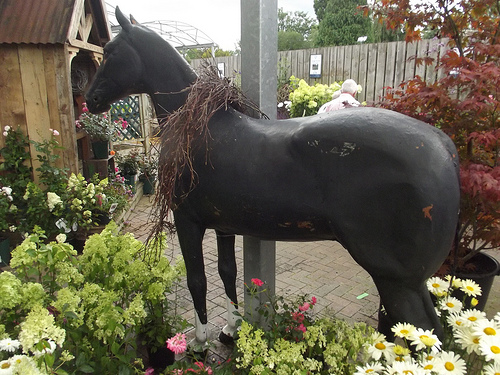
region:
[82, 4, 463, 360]
black statue of a horse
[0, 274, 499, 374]
white daisies around statue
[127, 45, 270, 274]
brown branches on statue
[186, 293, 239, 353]
statue has two white spots on legs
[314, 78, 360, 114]
older man behind statue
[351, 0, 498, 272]
red tree behind statue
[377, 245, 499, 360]
red tree in black pot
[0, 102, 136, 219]
roses behind statue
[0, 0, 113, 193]
wooden shed behind statue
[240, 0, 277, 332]
metal pole up against statue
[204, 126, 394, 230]
A sculpture of a horse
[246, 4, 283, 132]
A pillar in the photo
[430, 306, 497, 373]
White flowers in the garden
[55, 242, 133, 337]
Green flowers in the garden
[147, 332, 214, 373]
Red flowers in the garden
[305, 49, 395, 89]
A fence at the back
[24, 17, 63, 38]
Roof on the house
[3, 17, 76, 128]
A house in the photo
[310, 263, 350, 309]
Cabro paving in the photo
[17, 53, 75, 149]
Wooden wall on the house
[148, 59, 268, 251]
Brown vines around a horses neck area.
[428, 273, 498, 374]
White and yellow flowers at the backend of a horse.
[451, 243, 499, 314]
A black bucket with a tree in it behind a horse.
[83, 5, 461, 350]
A black horse with brown vines around it's neck.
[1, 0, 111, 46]
Metal worn red roof on a building.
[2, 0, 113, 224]
A barn in front of a horse.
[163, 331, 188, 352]
A lighter larger pink flower by a horses leg.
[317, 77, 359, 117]
A white haired man with his back turned to the camera.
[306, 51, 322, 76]
White sign on a fence across over by the old man.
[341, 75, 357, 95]
Back of a man's head with white hair.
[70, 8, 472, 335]
statue of a black horse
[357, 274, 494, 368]
white daisies with yellow center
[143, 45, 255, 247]
wreath of twigs and branches around horses neck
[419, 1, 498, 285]
tree with red leaves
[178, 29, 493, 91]
light brown wooded fence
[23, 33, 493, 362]
photograph of a horse statue in a garden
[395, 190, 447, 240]
black paint chipping off of horse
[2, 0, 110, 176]
wooden shed with a tin roof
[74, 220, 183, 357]
tall bright green flowers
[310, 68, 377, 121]
man with white hair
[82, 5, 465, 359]
The large statue of a horse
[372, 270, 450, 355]
The back legs of the statue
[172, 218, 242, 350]
The front leds of the statue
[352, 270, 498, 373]
Round white and yellow flowers beind the statue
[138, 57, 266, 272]
The horse collar made of twigs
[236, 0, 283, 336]
The silver square pole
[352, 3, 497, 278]
The tree with red leaves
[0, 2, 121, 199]
The wood shed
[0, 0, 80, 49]
The rusted tin roof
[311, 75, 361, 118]
The man with white hair